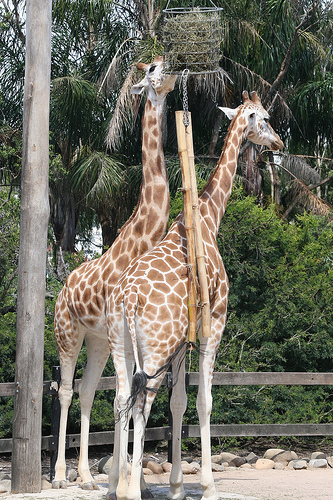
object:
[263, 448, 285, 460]
rock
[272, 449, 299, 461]
rock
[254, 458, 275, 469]
rock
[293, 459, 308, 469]
rock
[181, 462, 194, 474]
rock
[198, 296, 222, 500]
leg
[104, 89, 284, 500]
giraffe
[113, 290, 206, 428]
tail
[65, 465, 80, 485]
rocks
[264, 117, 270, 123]
eye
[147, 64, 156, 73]
eye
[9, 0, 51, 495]
trunk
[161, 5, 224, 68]
hay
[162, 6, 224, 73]
basket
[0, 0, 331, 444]
trees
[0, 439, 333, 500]
ground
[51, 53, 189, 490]
giraffe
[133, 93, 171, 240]
neck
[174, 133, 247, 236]
neck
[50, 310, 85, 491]
leg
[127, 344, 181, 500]
leg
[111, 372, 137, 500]
leg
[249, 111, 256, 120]
eye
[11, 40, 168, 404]
trunk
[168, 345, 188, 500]
leg